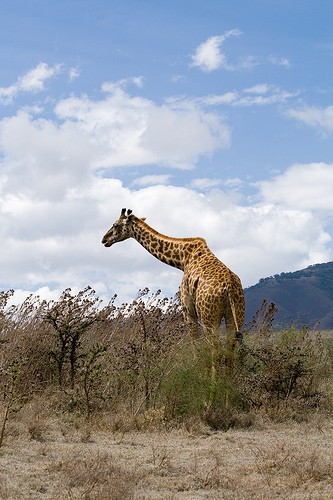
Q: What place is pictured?
A: It is a field.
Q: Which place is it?
A: It is a field.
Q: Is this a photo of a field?
A: Yes, it is showing a field.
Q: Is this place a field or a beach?
A: It is a field.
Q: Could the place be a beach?
A: No, it is a field.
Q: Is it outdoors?
A: Yes, it is outdoors.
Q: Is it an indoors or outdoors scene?
A: It is outdoors.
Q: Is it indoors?
A: No, it is outdoors.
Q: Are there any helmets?
A: No, there are no helmets.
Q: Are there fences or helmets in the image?
A: No, there are no helmets or fences.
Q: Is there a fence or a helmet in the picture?
A: No, there are no helmets or fences.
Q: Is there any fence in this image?
A: No, there are no fences.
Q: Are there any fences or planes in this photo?
A: No, there are no fences or planes.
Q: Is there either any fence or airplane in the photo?
A: No, there are no fences or airplanes.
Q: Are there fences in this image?
A: No, there are no fences.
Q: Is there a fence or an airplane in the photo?
A: No, there are no fences or airplanes.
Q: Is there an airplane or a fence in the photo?
A: No, there are no fences or airplanes.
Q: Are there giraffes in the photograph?
A: Yes, there is a giraffe.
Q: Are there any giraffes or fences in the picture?
A: Yes, there is a giraffe.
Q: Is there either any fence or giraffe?
A: Yes, there is a giraffe.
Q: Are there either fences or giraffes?
A: Yes, there is a giraffe.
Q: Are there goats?
A: No, there are no goats.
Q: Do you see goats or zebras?
A: No, there are no goats or zebras.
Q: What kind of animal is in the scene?
A: The animal is a giraffe.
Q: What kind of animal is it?
A: The animal is a giraffe.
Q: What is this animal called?
A: That is a giraffe.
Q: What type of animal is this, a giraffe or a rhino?
A: That is a giraffe.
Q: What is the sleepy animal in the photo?
A: The animal is a giraffe.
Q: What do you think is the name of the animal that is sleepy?
A: The animal is a giraffe.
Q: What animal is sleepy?
A: The animal is a giraffe.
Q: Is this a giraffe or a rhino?
A: This is a giraffe.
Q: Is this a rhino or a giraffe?
A: This is a giraffe.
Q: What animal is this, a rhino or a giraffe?
A: This is a giraffe.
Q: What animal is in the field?
A: The giraffe is in the field.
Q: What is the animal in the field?
A: The animal is a giraffe.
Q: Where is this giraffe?
A: The giraffe is in the field.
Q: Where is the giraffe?
A: The giraffe is in the field.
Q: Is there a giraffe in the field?
A: Yes, there is a giraffe in the field.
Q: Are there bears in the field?
A: No, there is a giraffe in the field.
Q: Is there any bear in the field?
A: No, there is a giraffe in the field.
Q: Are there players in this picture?
A: No, there are no players.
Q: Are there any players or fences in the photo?
A: No, there are no players or fences.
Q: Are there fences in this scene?
A: No, there are no fences.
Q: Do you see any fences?
A: No, there are no fences.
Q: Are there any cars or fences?
A: No, there are no fences or cars.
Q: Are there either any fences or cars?
A: No, there are no fences or cars.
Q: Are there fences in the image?
A: No, there are no fences.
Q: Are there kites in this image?
A: No, there are no kites.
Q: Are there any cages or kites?
A: No, there are no kites or cages.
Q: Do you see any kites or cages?
A: No, there are no kites or cages.